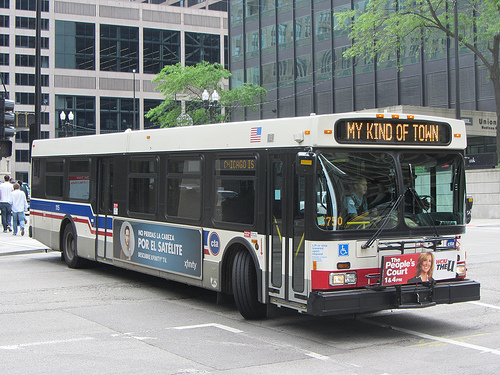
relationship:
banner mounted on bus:
[379, 252, 438, 284] [30, 111, 474, 308]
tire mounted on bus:
[60, 219, 93, 267] [30, 111, 474, 308]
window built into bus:
[205, 158, 259, 218] [30, 111, 474, 308]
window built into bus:
[162, 159, 202, 220] [30, 111, 474, 308]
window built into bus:
[129, 155, 157, 217] [30, 111, 474, 308]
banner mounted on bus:
[110, 213, 204, 281] [30, 111, 474, 308]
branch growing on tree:
[394, 20, 440, 44] [327, 0, 498, 102]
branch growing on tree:
[385, 9, 435, 23] [327, 0, 498, 102]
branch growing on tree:
[426, 1, 441, 27] [327, 0, 498, 102]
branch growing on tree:
[433, 1, 443, 11] [327, 0, 498, 102]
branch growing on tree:
[360, 3, 404, 14] [327, 0, 498, 102]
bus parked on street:
[30, 111, 482, 321] [2, 237, 492, 372]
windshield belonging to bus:
[312, 147, 465, 231] [50, 99, 485, 349]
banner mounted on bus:
[381, 251, 459, 286] [30, 111, 474, 308]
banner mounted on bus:
[111, 216, 204, 281] [30, 111, 482, 321]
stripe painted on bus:
[26, 197, 111, 232] [30, 111, 474, 308]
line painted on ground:
[369, 303, 499, 373] [0, 226, 484, 370]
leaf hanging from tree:
[165, 65, 171, 70] [144, 60, 264, 130]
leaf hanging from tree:
[200, 60, 204, 64] [144, 60, 264, 130]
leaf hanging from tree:
[200, 77, 205, 81] [144, 60, 264, 130]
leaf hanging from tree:
[427, 55, 430, 61] [340, 5, 497, 117]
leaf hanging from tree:
[395, 65, 401, 71] [340, 5, 497, 117]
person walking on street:
[8, 182, 28, 233] [0, 205, 484, 372]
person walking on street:
[0, 175, 11, 233] [0, 205, 484, 372]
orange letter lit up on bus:
[346, 122, 438, 142] [30, 111, 482, 321]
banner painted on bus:
[381, 251, 459, 286] [30, 111, 482, 321]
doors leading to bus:
[262, 146, 307, 312] [30, 111, 474, 308]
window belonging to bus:
[310, 145, 464, 229] [30, 111, 474, 308]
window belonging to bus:
[205, 158, 259, 218] [30, 111, 474, 308]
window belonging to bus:
[162, 159, 201, 220] [30, 111, 474, 308]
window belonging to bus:
[125, 159, 156, 216] [30, 111, 474, 308]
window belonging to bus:
[63, 159, 92, 201] [30, 111, 474, 308]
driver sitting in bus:
[335, 177, 373, 228] [30, 111, 482, 321]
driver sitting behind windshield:
[335, 177, 373, 228] [312, 147, 465, 231]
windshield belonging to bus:
[312, 147, 465, 231] [30, 111, 482, 321]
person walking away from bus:
[0, 175, 11, 233] [30, 111, 482, 321]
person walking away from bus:
[8, 182, 28, 233] [30, 111, 482, 321]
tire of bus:
[230, 255, 263, 317] [26, 119, 479, 318]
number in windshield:
[319, 214, 342, 228] [312, 147, 465, 231]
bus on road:
[30, 111, 482, 321] [0, 208, 299, 359]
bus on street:
[30, 111, 474, 308] [2, 237, 492, 372]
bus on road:
[30, 111, 482, 321] [1, 204, 496, 374]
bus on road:
[30, 111, 482, 321] [32, 229, 319, 362]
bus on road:
[30, 111, 482, 321] [5, 249, 497, 371]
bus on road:
[30, 111, 474, 308] [21, 227, 259, 369]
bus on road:
[30, 111, 482, 321] [0, 248, 267, 373]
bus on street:
[30, 111, 482, 321] [7, 254, 497, 371]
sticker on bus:
[233, 117, 291, 167] [26, 119, 479, 318]